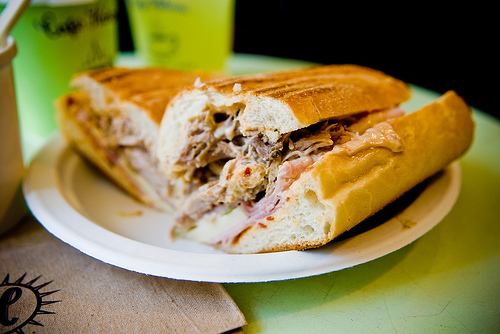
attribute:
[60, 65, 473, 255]
sandwich — half, hoagie, slice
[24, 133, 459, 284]
plate — white, round, wide, flat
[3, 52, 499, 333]
table — green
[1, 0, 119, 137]
cup — green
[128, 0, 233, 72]
cup — green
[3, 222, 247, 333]
napkin — brown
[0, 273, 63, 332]
logo — black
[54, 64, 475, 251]
bread — toasted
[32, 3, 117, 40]
writing — black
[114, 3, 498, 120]
background — black